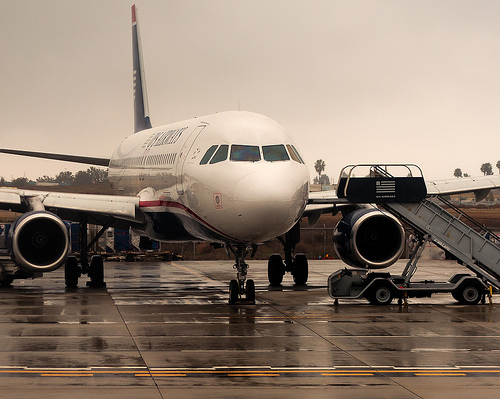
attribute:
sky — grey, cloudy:
[1, 4, 495, 188]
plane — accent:
[41, 79, 376, 309]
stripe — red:
[140, 182, 199, 232]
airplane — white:
[101, 7, 435, 313]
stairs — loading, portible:
[323, 135, 498, 307]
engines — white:
[4, 206, 415, 294]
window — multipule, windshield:
[229, 145, 260, 157]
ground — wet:
[1, 274, 498, 396]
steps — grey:
[336, 156, 499, 296]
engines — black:
[11, 206, 408, 281]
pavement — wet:
[2, 262, 496, 396]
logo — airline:
[141, 122, 193, 149]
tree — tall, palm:
[301, 155, 347, 195]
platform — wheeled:
[89, 230, 267, 395]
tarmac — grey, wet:
[0, 256, 499, 397]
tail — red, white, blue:
[120, 4, 171, 147]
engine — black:
[6, 189, 79, 276]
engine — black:
[337, 196, 410, 267]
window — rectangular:
[229, 141, 261, 164]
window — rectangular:
[260, 140, 289, 160]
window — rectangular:
[196, 140, 216, 163]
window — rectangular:
[211, 138, 230, 165]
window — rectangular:
[289, 140, 301, 163]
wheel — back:
[57, 248, 111, 297]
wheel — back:
[261, 250, 317, 293]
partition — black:
[342, 171, 428, 201]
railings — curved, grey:
[335, 153, 429, 182]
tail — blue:
[114, 14, 166, 132]